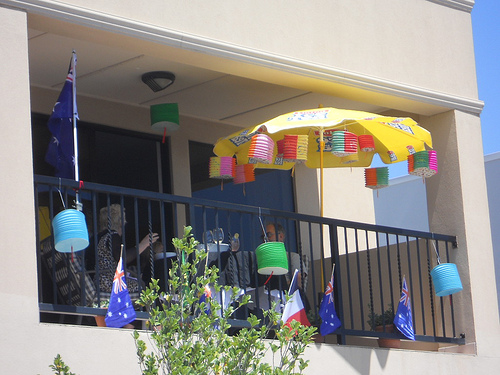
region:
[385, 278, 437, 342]
A blue white and red flag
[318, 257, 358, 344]
A blue white and red flag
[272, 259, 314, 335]
A blue white and red flag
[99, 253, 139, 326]
A blue white and red flag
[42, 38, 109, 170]
A blue white and red flag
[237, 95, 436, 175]
A yellow open umbrella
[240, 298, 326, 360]
A green tree branch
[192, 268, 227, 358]
A green tree branch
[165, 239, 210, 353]
A green tree branch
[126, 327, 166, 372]
A green tree branch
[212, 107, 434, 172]
the umbrella is yellow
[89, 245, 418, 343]
blue flags on the balcony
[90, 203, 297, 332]
people sitting at table on balcony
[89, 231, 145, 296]
woman's dress is leopard print and black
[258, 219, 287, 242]
man is wearing eye glasses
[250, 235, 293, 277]
green decoration on balcony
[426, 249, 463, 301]
blue decoration on balcony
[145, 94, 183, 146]
green decoration hanging from ceiling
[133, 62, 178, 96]
black light on ceiling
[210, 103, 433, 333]
Yellow sun umbrella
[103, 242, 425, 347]
World flags on a fence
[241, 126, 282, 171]
A multi colored lantern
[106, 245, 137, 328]
The Australian flag on a fence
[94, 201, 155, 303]
A woman sitting down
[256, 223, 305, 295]
A man sitting down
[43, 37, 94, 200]
The Australian flag standing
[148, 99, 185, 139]
A green lantern hanging from ceiling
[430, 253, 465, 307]
A blue lantern on fence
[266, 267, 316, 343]
The french flag on fence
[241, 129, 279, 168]
hanging paper style lantern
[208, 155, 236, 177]
hanging paper style lantern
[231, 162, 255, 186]
hanging paper style lantern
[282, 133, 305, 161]
hanging paper style lantern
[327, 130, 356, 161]
hanging paper style lantern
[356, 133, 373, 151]
hanging paper style lantern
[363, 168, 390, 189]
hanging paper style lantern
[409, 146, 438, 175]
hanging paper style lantern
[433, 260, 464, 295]
hanging paper style lantern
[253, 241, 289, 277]
hanging paper style lantern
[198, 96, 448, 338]
an umbrella color yellow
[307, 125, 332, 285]
shaft of umbrella is yellow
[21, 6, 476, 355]
people in a balcony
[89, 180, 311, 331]
people sits around a table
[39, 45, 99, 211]
a flag on a balcony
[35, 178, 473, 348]
rail of balcony is black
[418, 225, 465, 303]
a blue decoration hangs from balcony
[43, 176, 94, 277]
a blue decoration hangs from balcony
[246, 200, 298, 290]
a green decoration hangs from balcony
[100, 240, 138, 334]
a flags on a balcony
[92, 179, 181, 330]
woman sitting at table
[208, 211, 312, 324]
man sitting at table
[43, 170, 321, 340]
woman and man sitting at table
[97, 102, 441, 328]
yellow umbrella over man and woman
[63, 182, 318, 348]
man and woman sitting on balcony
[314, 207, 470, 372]
black metal rails on balcony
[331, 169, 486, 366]
black metal rails on tan balcony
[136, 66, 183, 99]
black light fixture on white ceiling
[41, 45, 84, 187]
Australian flag hanging on flag post attached to balcony rail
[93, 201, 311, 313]
Adult couple sitting on balcony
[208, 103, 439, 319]
Yellow shade umbrella with Chinese lanterns hanging from it